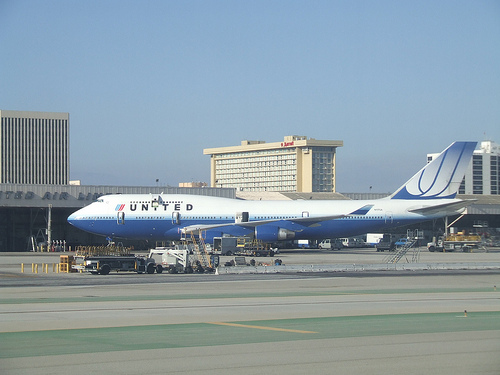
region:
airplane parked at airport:
[53, 129, 481, 284]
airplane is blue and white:
[57, 139, 499, 266]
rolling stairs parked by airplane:
[175, 224, 220, 283]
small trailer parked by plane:
[82, 243, 160, 278]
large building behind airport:
[181, 125, 344, 197]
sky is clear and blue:
[3, 1, 499, 193]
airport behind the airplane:
[1, 168, 499, 255]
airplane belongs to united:
[113, 193, 196, 218]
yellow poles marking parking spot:
[17, 259, 60, 273]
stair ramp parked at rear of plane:
[374, 220, 424, 270]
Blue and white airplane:
[68, 138, 483, 270]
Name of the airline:
[113, 201, 193, 214]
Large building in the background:
[202, 131, 344, 190]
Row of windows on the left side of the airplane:
[81, 213, 388, 223]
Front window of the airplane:
[95, 195, 106, 203]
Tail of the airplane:
[389, 140, 483, 214]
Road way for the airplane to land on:
[0, 249, 498, 372]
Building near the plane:
[1, 186, 236, 252]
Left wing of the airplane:
[166, 204, 371, 238]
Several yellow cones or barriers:
[15, 259, 61, 275]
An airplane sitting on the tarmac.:
[30, 135, 499, 306]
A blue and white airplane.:
[64, 123, 479, 273]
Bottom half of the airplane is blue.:
[62, 209, 452, 246]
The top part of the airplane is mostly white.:
[64, 141, 464, 213]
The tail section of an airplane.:
[397, 135, 477, 200]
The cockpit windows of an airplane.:
[84, 183, 111, 210]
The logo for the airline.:
[109, 200, 134, 216]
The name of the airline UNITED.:
[123, 192, 200, 219]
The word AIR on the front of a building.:
[43, 180, 71, 208]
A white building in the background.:
[199, 131, 344, 194]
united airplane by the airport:
[57, 138, 497, 259]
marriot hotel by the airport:
[210, 117, 355, 173]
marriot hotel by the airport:
[277, 135, 339, 185]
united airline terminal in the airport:
[5, 170, 61, 217]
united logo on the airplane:
[93, 192, 205, 222]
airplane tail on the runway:
[380, 117, 481, 238]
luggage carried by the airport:
[71, 240, 227, 286]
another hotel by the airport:
[8, 96, 97, 174]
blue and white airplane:
[67, 131, 478, 251]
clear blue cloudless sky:
[11, 10, 494, 109]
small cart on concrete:
[71, 250, 151, 280]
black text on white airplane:
[113, 197, 194, 215]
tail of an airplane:
[398, 133, 485, 206]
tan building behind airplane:
[200, 136, 348, 196]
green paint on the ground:
[12, 319, 310, 359]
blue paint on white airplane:
[70, 215, 415, 250]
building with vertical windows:
[0, 108, 71, 183]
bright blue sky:
[13, 4, 476, 111]